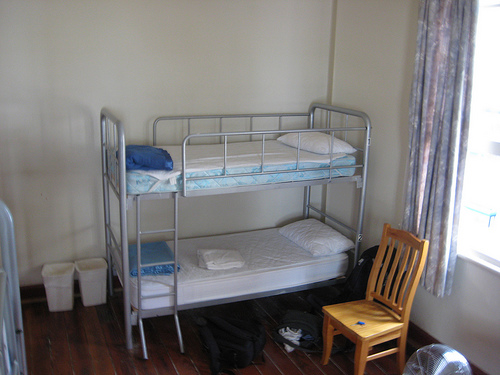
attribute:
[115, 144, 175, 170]
blanket — blue, folded, folded blue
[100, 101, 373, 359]
bed — silver, bunk bed, metallic grey, silver bunkbed, bunk bead, small, metal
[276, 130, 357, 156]
pillow — white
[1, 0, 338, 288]
wall — white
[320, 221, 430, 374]
chair — wooden, wood, brown, small, made of wood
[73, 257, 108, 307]
waste basket — small, white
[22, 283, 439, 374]
floor — dark wood, brown wood, wooden, dark hard wood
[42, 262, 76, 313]
waste basket — small, white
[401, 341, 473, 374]
fan — metal, top half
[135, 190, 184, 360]
ladder — metal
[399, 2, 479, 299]
curtain — open, dark colored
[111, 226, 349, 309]
mattress — lower, white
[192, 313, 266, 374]
back pack — black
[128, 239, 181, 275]
blanket — folded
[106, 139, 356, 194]
mattress — white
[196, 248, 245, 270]
sheet — folded white, white